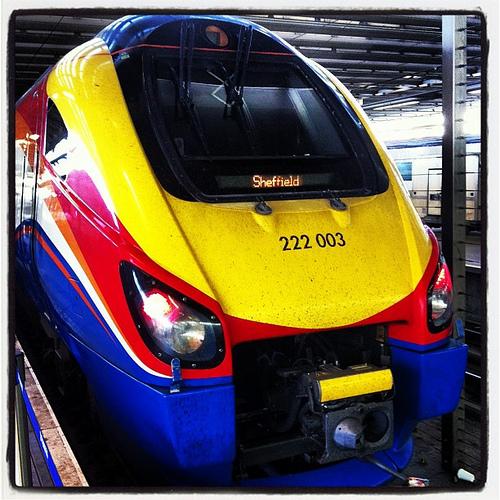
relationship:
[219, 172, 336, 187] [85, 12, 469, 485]
sign on front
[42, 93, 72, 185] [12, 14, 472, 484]
window on train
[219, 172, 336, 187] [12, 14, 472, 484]
sign on train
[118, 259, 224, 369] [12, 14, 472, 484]
headlight of train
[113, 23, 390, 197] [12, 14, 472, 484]
window of train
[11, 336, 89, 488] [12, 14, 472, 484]
platform next to train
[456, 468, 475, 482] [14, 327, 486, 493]
cup on ground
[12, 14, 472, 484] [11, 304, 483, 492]
train on track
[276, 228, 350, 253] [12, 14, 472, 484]
numbers on train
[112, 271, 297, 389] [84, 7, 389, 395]
light on train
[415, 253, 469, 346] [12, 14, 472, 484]
light on train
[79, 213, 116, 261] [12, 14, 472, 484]
red on train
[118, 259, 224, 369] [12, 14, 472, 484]
headlight on train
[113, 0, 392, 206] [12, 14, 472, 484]
windshield on train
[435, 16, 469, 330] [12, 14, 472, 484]
pole near train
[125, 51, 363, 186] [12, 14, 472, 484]
window on train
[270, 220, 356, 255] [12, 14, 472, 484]
222 003 on train